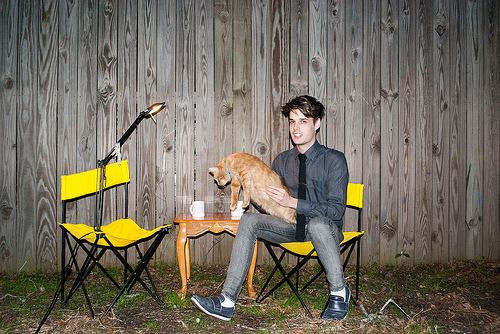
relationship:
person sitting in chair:
[191, 96, 353, 324] [259, 183, 362, 321]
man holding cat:
[191, 94, 352, 322] [208, 150, 301, 223]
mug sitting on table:
[189, 200, 206, 219] [175, 213, 261, 299]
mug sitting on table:
[230, 200, 247, 221] [175, 213, 261, 299]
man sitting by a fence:
[191, 94, 352, 322] [1, 1, 498, 274]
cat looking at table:
[208, 150, 301, 223] [175, 213, 261, 299]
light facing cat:
[94, 101, 166, 236] [208, 150, 301, 223]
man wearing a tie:
[191, 94, 352, 322] [295, 153, 307, 244]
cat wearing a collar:
[208, 150, 301, 223] [223, 157, 233, 182]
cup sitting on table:
[189, 201, 206, 220] [175, 213, 261, 299]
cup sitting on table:
[230, 202, 245, 220] [175, 213, 261, 299]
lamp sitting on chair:
[95, 102, 169, 234] [60, 159, 170, 317]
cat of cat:
[208, 152, 298, 224] [197, 133, 314, 228]